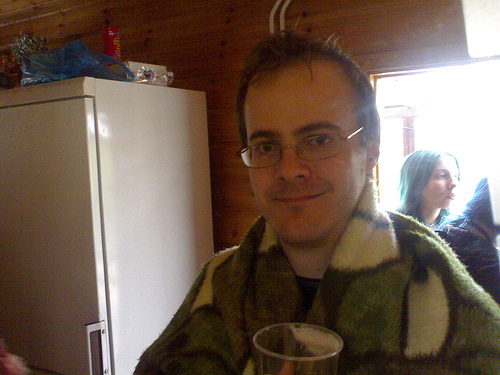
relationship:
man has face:
[130, 29, 499, 375] [242, 58, 369, 249]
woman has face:
[392, 151, 459, 235] [426, 156, 457, 209]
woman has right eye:
[392, 151, 459, 235] [436, 169, 448, 182]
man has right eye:
[130, 29, 499, 375] [248, 134, 278, 157]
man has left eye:
[130, 29, 499, 375] [301, 130, 338, 151]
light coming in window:
[381, 64, 499, 218] [367, 52, 499, 233]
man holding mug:
[130, 29, 499, 375] [251, 318, 348, 374]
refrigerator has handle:
[0, 75, 218, 374] [79, 317, 107, 373]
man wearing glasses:
[130, 29, 499, 375] [237, 120, 363, 171]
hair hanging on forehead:
[301, 58, 319, 87] [242, 77, 360, 124]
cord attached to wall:
[262, 2, 282, 33] [2, 2, 468, 252]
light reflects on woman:
[381, 64, 499, 218] [392, 151, 459, 235]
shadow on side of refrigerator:
[181, 81, 217, 274] [0, 75, 218, 374]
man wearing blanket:
[130, 29, 499, 375] [128, 177, 497, 374]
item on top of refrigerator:
[113, 57, 178, 89] [0, 75, 218, 374]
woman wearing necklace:
[392, 151, 459, 235] [426, 221, 438, 233]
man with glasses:
[130, 29, 499, 375] [237, 120, 363, 171]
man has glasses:
[130, 29, 499, 375] [237, 120, 363, 171]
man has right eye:
[130, 29, 499, 375] [436, 169, 448, 182]